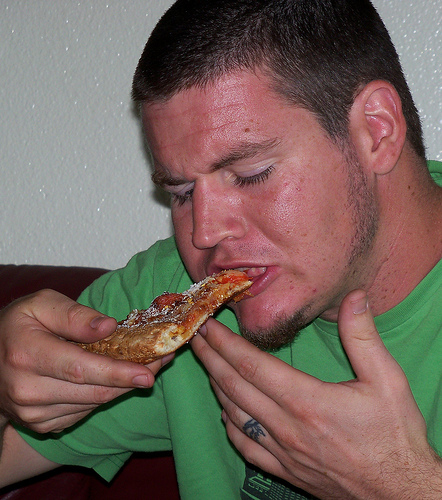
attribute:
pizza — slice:
[69, 268, 255, 367]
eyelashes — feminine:
[172, 190, 194, 201]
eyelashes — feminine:
[228, 169, 275, 184]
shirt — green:
[8, 160, 441, 497]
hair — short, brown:
[128, 6, 439, 117]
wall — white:
[1, 1, 439, 278]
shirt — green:
[17, 206, 432, 498]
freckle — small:
[413, 192, 419, 197]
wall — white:
[10, 38, 131, 183]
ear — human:
[346, 79, 403, 170]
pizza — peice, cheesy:
[83, 263, 254, 362]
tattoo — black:
[219, 408, 304, 454]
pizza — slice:
[84, 263, 233, 362]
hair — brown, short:
[135, 11, 431, 160]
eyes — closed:
[168, 154, 275, 194]